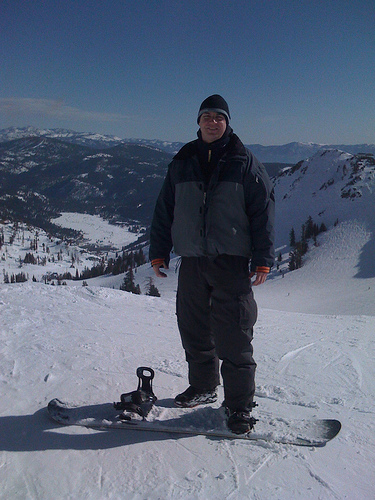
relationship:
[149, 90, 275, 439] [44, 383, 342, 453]
guy on a snowboard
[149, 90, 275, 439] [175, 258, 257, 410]
guy in jacket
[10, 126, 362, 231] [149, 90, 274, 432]
mountains behind a guy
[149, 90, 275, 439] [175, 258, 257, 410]
guy with jacket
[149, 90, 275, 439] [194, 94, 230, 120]
guy with hat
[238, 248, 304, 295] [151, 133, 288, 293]
cuff on coat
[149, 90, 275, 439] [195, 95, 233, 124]
guy wearing cap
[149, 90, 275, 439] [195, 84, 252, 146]
guy has cap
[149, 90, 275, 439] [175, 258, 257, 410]
guy has jacket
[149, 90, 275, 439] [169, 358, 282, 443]
guy has boots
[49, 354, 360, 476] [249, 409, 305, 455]
ski covered with snow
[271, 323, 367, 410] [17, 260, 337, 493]
snow on hill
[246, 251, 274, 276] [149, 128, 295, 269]
cuff on coat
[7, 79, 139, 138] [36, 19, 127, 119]
clouds in sky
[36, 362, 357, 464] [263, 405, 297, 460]
snowboard covered in snow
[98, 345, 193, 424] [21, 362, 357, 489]
foot brace of snowboard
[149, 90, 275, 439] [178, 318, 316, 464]
guy in boots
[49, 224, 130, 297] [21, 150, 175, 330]
trees in background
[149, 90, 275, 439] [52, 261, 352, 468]
guy on hill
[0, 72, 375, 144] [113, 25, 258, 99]
clouds in sky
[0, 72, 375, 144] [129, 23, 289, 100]
clouds in sky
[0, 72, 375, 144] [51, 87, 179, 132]
clouds in sky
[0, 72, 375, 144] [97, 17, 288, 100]
clouds in sky